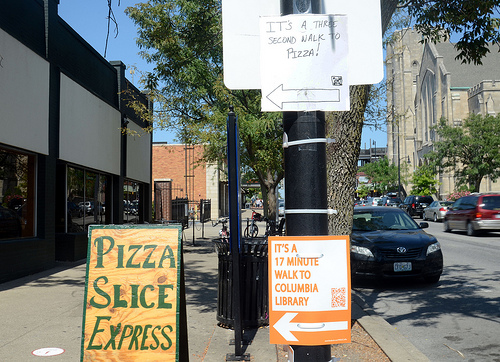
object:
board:
[82, 223, 187, 361]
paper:
[258, 13, 350, 112]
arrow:
[265, 83, 341, 110]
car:
[347, 205, 443, 284]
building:
[0, 0, 153, 280]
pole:
[283, 3, 330, 361]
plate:
[393, 262, 413, 272]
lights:
[350, 242, 442, 258]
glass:
[352, 210, 419, 230]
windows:
[0, 151, 142, 239]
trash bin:
[212, 235, 264, 331]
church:
[382, 19, 500, 217]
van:
[441, 192, 500, 236]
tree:
[120, 0, 500, 197]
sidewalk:
[0, 200, 393, 361]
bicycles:
[210, 216, 266, 239]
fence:
[172, 196, 212, 230]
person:
[181, 203, 191, 229]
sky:
[57, 0, 492, 146]